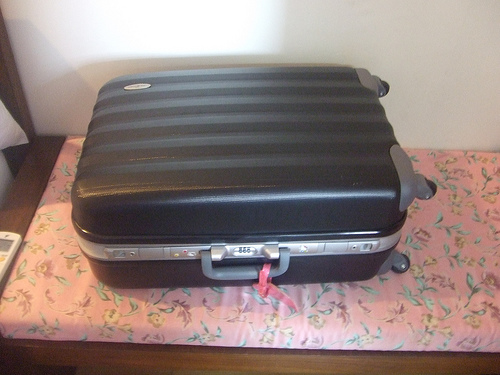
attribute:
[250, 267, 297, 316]
ribbon —  red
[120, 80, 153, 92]
logo — silver, oval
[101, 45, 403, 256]
luggage — black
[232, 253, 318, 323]
ribbon — pink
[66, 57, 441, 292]
suitcase — gray, closed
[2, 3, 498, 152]
wall — white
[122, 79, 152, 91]
disk — silver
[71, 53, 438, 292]
case — black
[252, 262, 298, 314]
ribbon —  pink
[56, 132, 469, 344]
mat — pink, gray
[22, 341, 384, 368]
table — wooden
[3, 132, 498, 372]
table — dark, wooden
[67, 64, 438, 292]
luggage — black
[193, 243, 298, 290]
handle — gray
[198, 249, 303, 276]
handle —   luggage's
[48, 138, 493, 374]
fabric — pink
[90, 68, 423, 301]
case — black, silver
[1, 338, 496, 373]
frame —  wooden,  furniture's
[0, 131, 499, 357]
cushion — pink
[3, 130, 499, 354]
cover — pink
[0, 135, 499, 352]
flowers — multicolored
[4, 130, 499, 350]
design — small, floral print